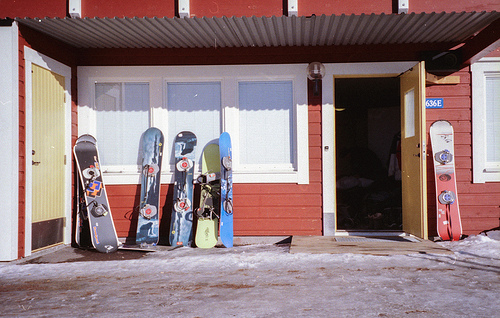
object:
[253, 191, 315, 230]
siding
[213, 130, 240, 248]
snowboard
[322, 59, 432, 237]
door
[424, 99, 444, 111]
address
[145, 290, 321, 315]
concrete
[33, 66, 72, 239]
door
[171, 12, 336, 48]
overhang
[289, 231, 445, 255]
ramp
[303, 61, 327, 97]
light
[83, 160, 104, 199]
graphics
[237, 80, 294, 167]
blinds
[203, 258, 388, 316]
cement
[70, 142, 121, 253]
snowboards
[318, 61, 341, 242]
frame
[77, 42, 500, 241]
business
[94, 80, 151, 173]
windows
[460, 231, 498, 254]
snow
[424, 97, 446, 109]
636e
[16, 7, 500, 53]
awning